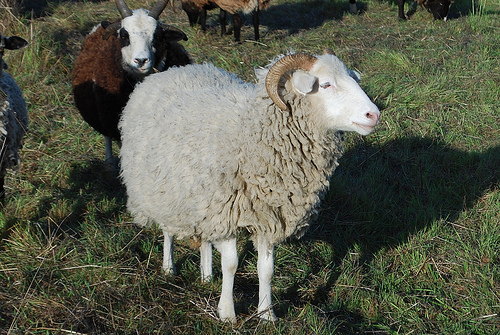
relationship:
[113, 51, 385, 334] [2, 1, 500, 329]
sheep in pasture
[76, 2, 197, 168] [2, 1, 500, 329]
sheep in pasture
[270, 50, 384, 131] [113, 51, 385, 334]
head of sheep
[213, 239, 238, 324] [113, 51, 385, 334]
leg of sheep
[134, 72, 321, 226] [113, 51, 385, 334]
fur of sheep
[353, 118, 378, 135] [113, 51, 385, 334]
mouth of ram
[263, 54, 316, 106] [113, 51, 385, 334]
horn of ram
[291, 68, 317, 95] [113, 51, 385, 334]
ear of ram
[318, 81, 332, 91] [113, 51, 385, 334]
eye of ram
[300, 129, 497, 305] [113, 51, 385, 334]
shadow of ram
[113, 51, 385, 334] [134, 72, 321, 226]
ram has coat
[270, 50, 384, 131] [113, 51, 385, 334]
head of ram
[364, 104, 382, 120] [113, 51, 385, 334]
nose of ram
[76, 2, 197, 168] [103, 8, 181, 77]
ram has head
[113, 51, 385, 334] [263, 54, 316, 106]
sheep has horn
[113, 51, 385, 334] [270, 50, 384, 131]
sheep has head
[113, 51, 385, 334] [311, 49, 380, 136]
sheep has face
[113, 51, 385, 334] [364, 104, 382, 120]
sheep has nose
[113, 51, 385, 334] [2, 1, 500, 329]
sheep in field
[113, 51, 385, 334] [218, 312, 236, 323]
sheep has hoof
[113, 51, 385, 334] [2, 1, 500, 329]
sheep in grass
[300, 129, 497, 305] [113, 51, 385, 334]
shadow of sheep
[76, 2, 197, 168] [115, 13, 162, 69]
sheep has face